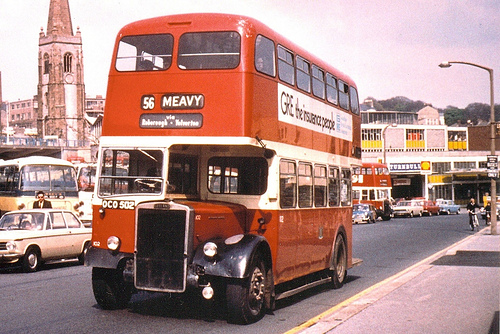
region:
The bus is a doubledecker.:
[76, 10, 383, 322]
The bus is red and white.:
[70, 10, 376, 325]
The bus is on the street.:
[3, 9, 478, 332]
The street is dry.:
[1, 203, 498, 332]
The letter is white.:
[161, 93, 174, 108]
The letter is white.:
[170, 88, 180, 108]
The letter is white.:
[178, 91, 187, 108]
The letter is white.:
[183, 86, 194, 110]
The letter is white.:
[193, 89, 204, 110]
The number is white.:
[141, 93, 155, 112]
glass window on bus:
[113, 33, 170, 70]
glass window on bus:
[175, 30, 239, 68]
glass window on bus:
[254, 33, 274, 77]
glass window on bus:
[278, 45, 295, 90]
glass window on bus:
[294, 57, 312, 92]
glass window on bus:
[311, 62, 325, 98]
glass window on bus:
[325, 72, 339, 105]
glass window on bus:
[281, 156, 298, 204]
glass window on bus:
[298, 160, 312, 209]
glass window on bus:
[313, 163, 328, 206]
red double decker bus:
[96, 12, 352, 314]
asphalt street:
[0, 195, 485, 331]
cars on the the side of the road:
[0, 140, 85, 256]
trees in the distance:
[347, 70, 495, 122]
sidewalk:
[288, 195, 498, 330]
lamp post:
[436, 52, 497, 233]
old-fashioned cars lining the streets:
[318, 177, 463, 217]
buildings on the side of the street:
[353, 97, 495, 202]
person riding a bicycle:
[460, 195, 475, 232]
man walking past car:
[34, 192, 57, 217]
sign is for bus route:
[135, 87, 209, 112]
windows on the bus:
[233, 30, 358, 116]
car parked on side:
[0, 231, 92, 273]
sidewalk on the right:
[432, 268, 479, 317]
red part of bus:
[245, 210, 336, 288]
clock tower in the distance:
[34, 13, 91, 147]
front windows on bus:
[112, 26, 242, 78]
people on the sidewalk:
[469, 186, 490, 234]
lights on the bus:
[200, 232, 225, 263]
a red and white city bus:
[91, 13, 362, 319]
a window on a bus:
[205, 155, 273, 199]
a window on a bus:
[248, 33, 278, 83]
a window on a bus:
[278, 157, 294, 209]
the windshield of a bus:
[101, 149, 161, 195]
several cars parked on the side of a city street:
[355, 197, 462, 222]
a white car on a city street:
[0, 206, 95, 277]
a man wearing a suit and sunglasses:
[29, 190, 53, 210]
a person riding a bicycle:
[463, 194, 484, 229]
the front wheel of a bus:
[223, 248, 271, 324]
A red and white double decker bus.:
[91, 22, 364, 324]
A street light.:
[437, 58, 495, 233]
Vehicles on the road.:
[1, 15, 491, 323]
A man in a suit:
[29, 185, 56, 224]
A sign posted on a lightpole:
[482, 151, 498, 179]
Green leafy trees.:
[354, 95, 498, 127]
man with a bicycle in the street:
[465, 197, 480, 229]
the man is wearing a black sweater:
[465, 192, 480, 227]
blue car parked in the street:
[438, 195, 461, 217]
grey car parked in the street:
[1, 208, 88, 273]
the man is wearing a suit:
[30, 188, 51, 220]